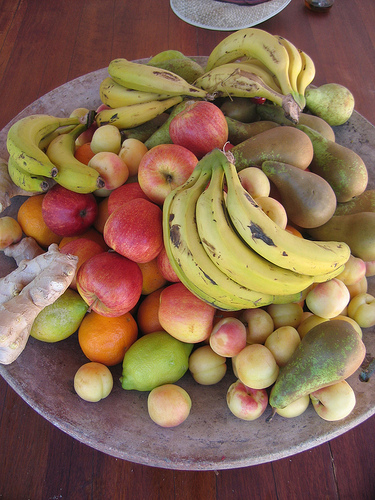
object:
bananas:
[161, 149, 351, 311]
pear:
[269, 319, 367, 409]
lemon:
[118, 330, 194, 393]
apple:
[102, 197, 164, 264]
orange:
[77, 307, 139, 366]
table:
[1, 2, 375, 500]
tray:
[0, 54, 374, 473]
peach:
[73, 363, 113, 403]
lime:
[30, 288, 90, 344]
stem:
[265, 406, 276, 425]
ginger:
[0, 243, 78, 365]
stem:
[107, 247, 115, 253]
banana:
[46, 115, 106, 193]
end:
[96, 176, 106, 188]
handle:
[190, 148, 237, 179]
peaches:
[207, 314, 248, 359]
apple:
[78, 250, 144, 315]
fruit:
[18, 194, 61, 249]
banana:
[218, 149, 352, 275]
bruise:
[247, 220, 278, 248]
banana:
[6, 114, 72, 178]